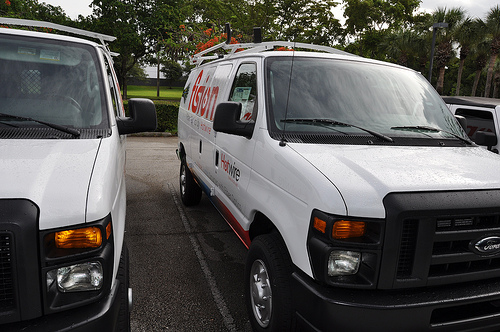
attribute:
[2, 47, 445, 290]
trucks — parked, white, side by side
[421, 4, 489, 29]
shower — slight rain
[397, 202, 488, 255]
grill — black, flat black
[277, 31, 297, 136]
antenna — radio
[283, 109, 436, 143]
windshield wipers — black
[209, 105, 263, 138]
mirror — rear side, black, side, rear view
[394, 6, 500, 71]
trees — palm, swaying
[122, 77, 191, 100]
grass — green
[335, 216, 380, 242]
light — orange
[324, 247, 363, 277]
headlight — off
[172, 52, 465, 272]
van — white, red, black, large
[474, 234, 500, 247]
emblem — ford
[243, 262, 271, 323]
hubcap — silver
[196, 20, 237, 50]
flowers — red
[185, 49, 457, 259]
vehicle — parked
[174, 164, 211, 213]
wheel — rear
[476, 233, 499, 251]
logo — manufacturer, ford, corperate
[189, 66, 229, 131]
lettering — red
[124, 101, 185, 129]
hedges — green